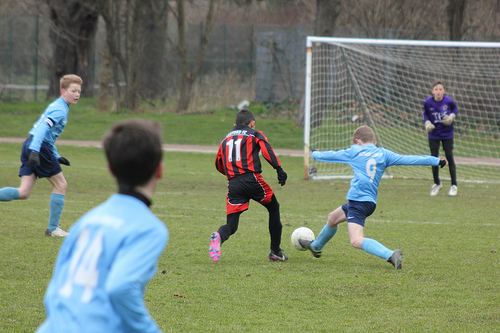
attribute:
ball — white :
[287, 227, 323, 258]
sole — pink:
[195, 219, 231, 273]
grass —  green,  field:
[0, 110, 498, 330]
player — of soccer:
[1, 61, 78, 246]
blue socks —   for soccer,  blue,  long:
[359, 238, 393, 263]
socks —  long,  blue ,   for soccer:
[38, 189, 68, 232]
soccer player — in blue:
[289, 110, 465, 282]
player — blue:
[310, 127, 412, 264]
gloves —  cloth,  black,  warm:
[274, 167, 292, 192]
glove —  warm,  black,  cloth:
[57, 151, 74, 166]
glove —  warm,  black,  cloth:
[28, 151, 43, 162]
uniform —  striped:
[216, 126, 281, 204]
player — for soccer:
[210, 110, 291, 262]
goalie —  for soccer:
[420, 81, 468, 200]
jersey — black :
[209, 128, 281, 183]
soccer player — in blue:
[422, 81, 461, 198]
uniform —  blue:
[308, 147, 437, 262]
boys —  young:
[0, 60, 485, 330]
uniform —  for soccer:
[304, 140, 451, 231]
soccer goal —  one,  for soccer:
[289, 9, 496, 183]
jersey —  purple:
[421, 97, 459, 129]